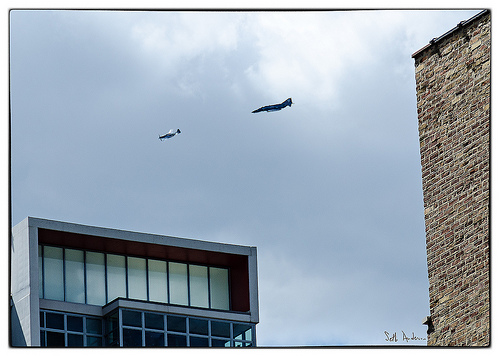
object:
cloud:
[105, 16, 386, 89]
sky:
[11, 11, 483, 345]